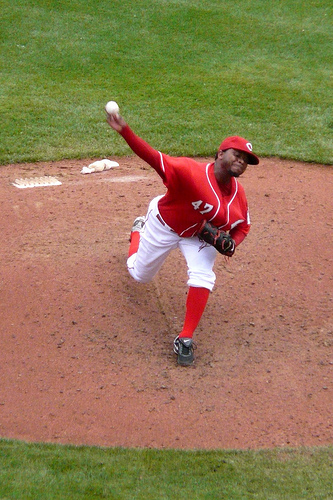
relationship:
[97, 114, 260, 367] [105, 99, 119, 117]
baseball player throwing ball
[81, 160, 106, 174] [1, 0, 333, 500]
bag sitting on ground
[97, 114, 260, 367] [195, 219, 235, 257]
baseball player wearing baseball glove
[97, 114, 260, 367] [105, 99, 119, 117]
baseball player holding ball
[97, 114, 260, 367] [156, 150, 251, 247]
baseball player wearing top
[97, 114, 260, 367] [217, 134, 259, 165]
baseball player wearing baseball cap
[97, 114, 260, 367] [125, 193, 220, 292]
baseball player wearing pants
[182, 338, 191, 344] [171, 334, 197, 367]
logo on front of shoe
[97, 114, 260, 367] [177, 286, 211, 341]
baseball player wearing sock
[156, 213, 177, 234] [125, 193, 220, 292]
cloth belt worn on pants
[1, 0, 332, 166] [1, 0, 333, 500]
grass on outside of ground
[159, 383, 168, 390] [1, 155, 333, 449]
stone on top of pitcher's mound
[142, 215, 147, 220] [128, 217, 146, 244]
cleat worn on foot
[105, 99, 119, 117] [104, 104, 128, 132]
ball held in hand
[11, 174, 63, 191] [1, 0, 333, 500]
base sitting on ground